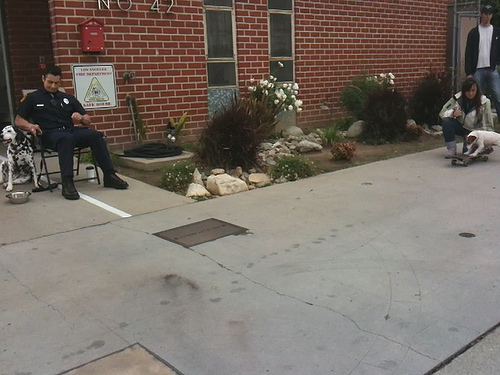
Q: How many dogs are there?
A: Two.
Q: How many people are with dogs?
A: Two.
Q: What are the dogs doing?
A: Sitting.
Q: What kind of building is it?
A: Brick.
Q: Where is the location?
A: Fire station.